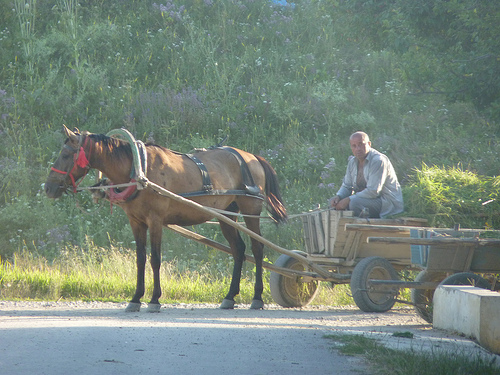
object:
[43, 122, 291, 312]
horse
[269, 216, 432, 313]
buggy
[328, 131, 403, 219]
man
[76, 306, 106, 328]
road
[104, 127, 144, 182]
yoke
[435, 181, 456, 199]
grass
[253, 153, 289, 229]
tail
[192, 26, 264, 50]
hill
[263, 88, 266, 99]
flowers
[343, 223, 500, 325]
cart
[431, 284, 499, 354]
block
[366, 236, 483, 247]
poles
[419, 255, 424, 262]
planks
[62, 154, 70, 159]
eyes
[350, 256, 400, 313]
wheel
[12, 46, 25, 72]
bushes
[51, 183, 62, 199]
mouth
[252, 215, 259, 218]
rope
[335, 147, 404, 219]
shirt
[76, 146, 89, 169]
bridle